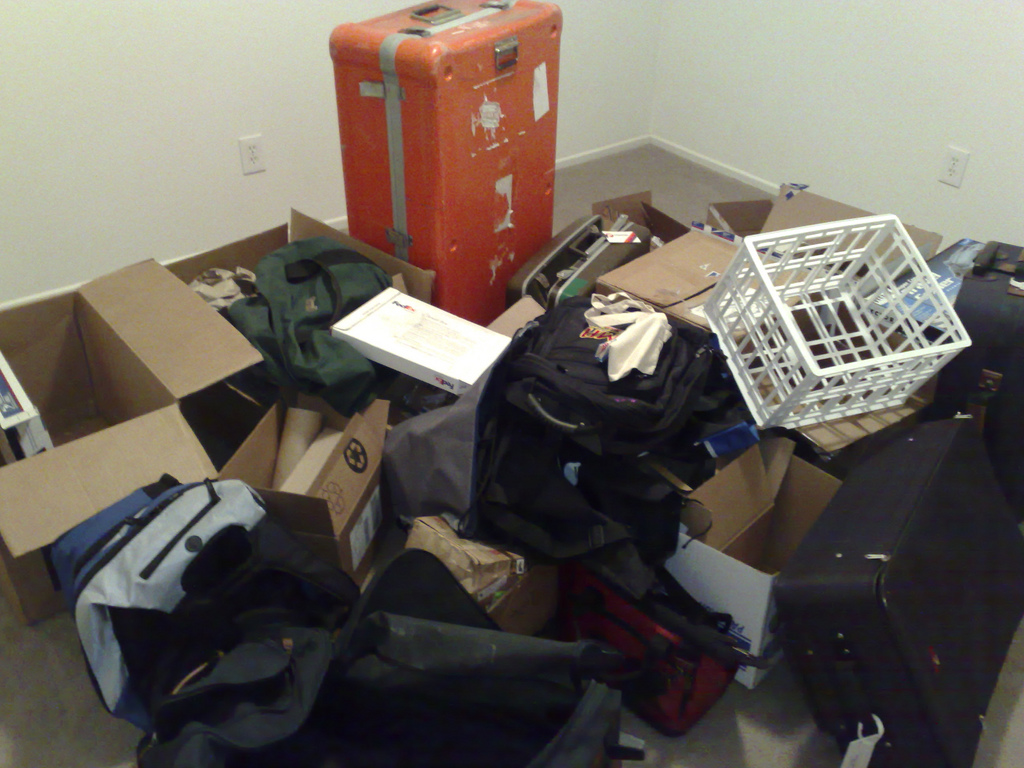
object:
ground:
[16, 235, 292, 599]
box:
[0, 257, 268, 627]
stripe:
[363, 30, 429, 265]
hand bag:
[567, 572, 739, 732]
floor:
[3, 605, 145, 766]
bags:
[230, 230, 416, 409]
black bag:
[471, 291, 717, 554]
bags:
[303, 548, 646, 766]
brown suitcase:
[505, 209, 654, 311]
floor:
[551, 131, 749, 208]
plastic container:
[699, 209, 970, 430]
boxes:
[160, 209, 442, 432]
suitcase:
[875, 234, 1024, 517]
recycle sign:
[342, 438, 368, 473]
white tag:
[843, 717, 888, 765]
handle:
[829, 652, 875, 726]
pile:
[57, 213, 982, 760]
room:
[0, 1, 1023, 762]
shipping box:
[336, 280, 519, 399]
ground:
[656, 613, 1022, 762]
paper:
[580, 282, 676, 382]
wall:
[3, 1, 238, 243]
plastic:
[704, 211, 970, 434]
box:
[741, 343, 941, 476]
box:
[328, 0, 566, 332]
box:
[213, 400, 395, 592]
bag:
[44, 476, 356, 725]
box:
[654, 450, 849, 692]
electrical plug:
[239, 134, 264, 175]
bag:
[144, 603, 578, 753]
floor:
[647, 696, 854, 766]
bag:
[756, 413, 1024, 767]